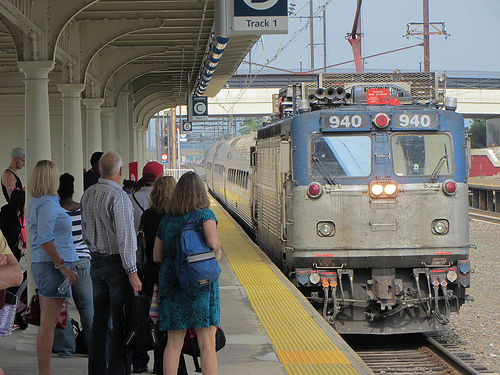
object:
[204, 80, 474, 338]
train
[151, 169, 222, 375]
people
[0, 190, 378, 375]
platform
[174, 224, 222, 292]
bag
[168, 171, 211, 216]
hair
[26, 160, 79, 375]
lady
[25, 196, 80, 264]
shirt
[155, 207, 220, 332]
dress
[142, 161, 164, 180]
cap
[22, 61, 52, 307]
columns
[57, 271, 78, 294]
bottle